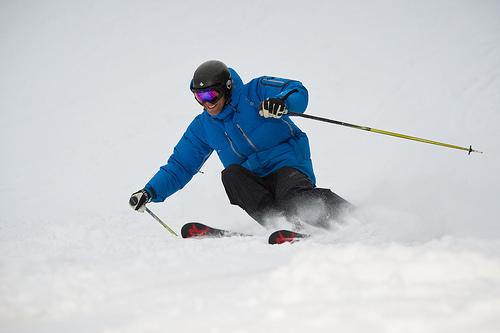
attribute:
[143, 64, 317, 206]
jacket — blue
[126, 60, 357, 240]
skier — blue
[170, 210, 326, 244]
ski shoes — red pattern underneath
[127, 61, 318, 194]
coat — blue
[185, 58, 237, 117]
helmet — black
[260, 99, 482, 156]
ski pole — yellow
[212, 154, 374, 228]
pants — black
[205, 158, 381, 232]
pants — black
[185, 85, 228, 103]
goggles — large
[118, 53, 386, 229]
man — skiing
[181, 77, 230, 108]
goggles — snow goggles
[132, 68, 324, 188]
jacket — blue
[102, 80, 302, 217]
gloves — black, white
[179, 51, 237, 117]
helmet — black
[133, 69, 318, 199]
jacket — blue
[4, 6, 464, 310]
slope — snowy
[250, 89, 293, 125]
glove — black, trimmed in white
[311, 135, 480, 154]
pole — yellow and black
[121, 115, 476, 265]
skis — pair and black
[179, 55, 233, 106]
helmet — black,  black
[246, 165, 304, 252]
pants —  black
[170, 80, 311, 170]
jacket —  blue